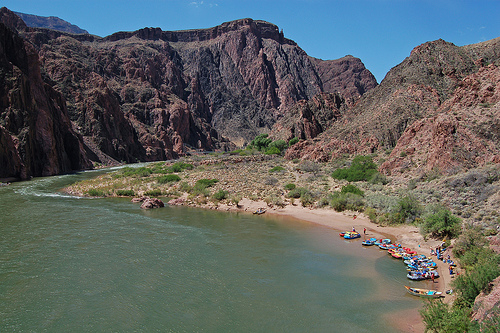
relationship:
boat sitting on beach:
[343, 231, 361, 239] [297, 204, 470, 309]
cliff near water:
[8, 20, 379, 178] [0, 158, 443, 331]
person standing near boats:
[349, 210, 361, 222] [332, 210, 444, 308]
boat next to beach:
[402, 284, 446, 301] [61, 149, 478, 331]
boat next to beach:
[342, 231, 359, 241] [61, 149, 478, 331]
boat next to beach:
[337, 229, 357, 236] [61, 149, 478, 331]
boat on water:
[343, 231, 361, 239] [7, 162, 415, 330]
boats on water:
[362, 234, 392, 247] [7, 162, 415, 330]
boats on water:
[387, 242, 405, 253] [7, 162, 415, 330]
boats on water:
[406, 269, 438, 280] [7, 162, 415, 330]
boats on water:
[410, 254, 440, 276] [7, 162, 415, 330]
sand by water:
[247, 207, 352, 227] [0, 194, 380, 331]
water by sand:
[0, 194, 380, 331] [246, 202, 375, 227]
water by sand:
[0, 206, 281, 331] [296, 212, 381, 226]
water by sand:
[0, 194, 380, 331] [284, 207, 341, 229]